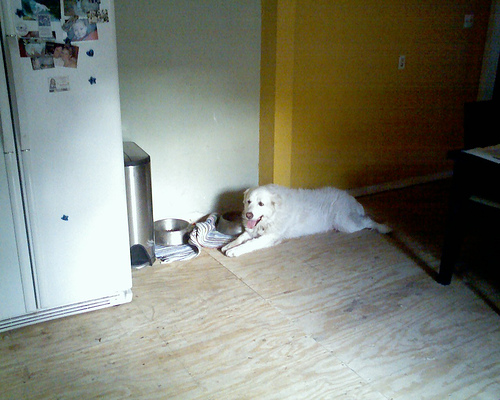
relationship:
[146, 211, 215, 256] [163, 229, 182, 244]
dog food inside of bowl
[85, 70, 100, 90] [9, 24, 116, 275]
magnet attached to fridge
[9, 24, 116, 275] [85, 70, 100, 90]
fridge attached to magnet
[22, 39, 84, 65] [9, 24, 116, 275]
photograph attached to fridge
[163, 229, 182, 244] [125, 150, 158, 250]
bowl next to garbage can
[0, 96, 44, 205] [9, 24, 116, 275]
handles attached to fridge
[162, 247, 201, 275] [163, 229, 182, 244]
rug under bowl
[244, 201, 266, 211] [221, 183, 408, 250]
eyes attached to dog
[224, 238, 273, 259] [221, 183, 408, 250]
front legs of dog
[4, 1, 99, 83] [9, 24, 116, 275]
pictures attached to fridge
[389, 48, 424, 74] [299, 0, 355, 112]
socket attached to wall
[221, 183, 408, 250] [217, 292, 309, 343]
dog on ground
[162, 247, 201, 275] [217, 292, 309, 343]
rug on top of ground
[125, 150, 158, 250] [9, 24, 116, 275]
garbage can next to fridge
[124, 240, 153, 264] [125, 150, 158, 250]
pedal attached to garbage can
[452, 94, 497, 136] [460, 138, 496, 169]
chair at table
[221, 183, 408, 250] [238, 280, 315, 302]
dog laying on floor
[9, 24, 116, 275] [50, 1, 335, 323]
fridge inside of kitchen